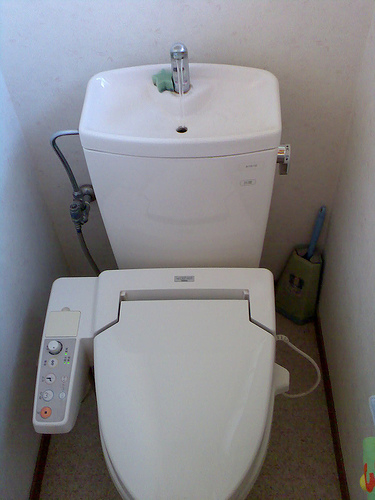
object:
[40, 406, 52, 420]
button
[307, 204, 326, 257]
handle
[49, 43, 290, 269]
toilet bowl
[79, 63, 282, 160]
lid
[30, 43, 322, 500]
toilet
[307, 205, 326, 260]
brush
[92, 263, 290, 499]
toilet bowl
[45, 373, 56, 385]
button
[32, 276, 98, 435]
armrest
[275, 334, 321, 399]
wire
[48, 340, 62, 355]
white knob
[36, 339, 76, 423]
button panel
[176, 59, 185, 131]
water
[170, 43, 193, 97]
faucet